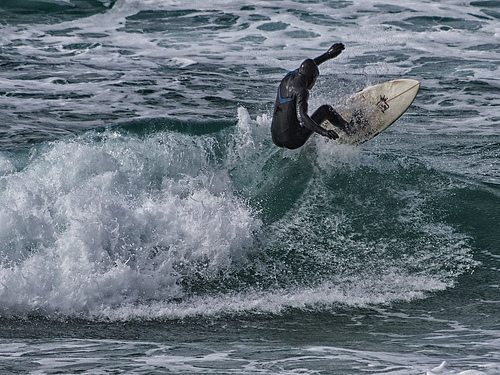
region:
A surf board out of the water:
[375, 85, 406, 105]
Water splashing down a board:
[357, 96, 374, 111]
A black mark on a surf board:
[376, 98, 388, 112]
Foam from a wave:
[48, 160, 127, 223]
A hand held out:
[328, 41, 345, 52]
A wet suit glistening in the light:
[284, 78, 298, 93]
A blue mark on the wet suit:
[278, 93, 292, 103]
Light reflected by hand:
[327, 49, 334, 52]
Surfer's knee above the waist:
[320, 105, 330, 116]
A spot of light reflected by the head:
[299, 63, 305, 69]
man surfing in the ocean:
[257, 27, 427, 171]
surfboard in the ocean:
[331, 65, 428, 135]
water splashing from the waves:
[11, 128, 215, 276]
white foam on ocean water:
[148, 351, 194, 368]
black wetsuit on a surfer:
[270, 76, 314, 141]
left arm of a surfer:
[319, 35, 347, 69]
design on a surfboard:
[371, 96, 392, 115]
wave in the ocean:
[315, 150, 490, 279]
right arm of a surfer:
[294, 100, 345, 143]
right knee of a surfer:
[318, 96, 339, 125]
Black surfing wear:
[267, 80, 346, 147]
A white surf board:
[354, 77, 431, 137]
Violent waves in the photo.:
[71, 188, 258, 274]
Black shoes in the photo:
[340, 111, 365, 136]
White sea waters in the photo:
[157, 26, 233, 66]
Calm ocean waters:
[260, 324, 340, 371]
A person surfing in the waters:
[266, 42, 356, 154]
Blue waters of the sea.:
[148, 14, 190, 36]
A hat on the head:
[293, 57, 319, 78]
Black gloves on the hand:
[320, 122, 338, 143]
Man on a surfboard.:
[252, 36, 439, 177]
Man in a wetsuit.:
[265, 45, 417, 169]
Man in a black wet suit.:
[263, 37, 415, 176]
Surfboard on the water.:
[227, 27, 457, 161]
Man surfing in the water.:
[261, 15, 453, 192]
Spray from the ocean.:
[164, 80, 368, 260]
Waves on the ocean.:
[140, 124, 409, 344]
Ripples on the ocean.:
[42, 25, 190, 155]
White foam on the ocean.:
[205, 165, 432, 371]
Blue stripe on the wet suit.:
[262, 64, 303, 99]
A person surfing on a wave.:
[265, 40, 418, 149]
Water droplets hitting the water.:
[2, 307, 497, 338]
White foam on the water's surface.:
[0, 5, 485, 112]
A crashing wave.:
[6, 120, 246, 325]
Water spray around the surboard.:
[305, 72, 415, 147]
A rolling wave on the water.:
[100, 111, 250, 131]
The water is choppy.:
[1, 5, 496, 110]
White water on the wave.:
[5, 130, 250, 315]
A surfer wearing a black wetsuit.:
[270, 40, 365, 150]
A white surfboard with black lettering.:
[311, 75, 424, 148]